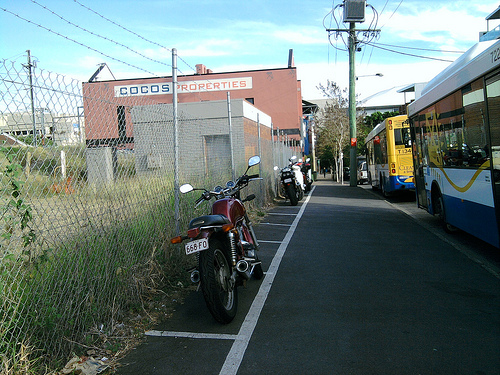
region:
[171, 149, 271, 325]
Motorcycle leaning against fence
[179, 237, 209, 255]
License on motorcycle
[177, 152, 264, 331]
Motorcycle next to bus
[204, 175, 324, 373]
White line next to motorcycles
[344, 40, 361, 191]
Wooden post is green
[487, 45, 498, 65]
722 on top of bus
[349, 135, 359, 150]
Red sign on wooden post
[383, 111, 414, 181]
Back of bus is yellow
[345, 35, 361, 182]
Wooden post next to bus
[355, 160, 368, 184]
White car in front of bus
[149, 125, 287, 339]
red motorcycle is parked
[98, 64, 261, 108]
white sign on building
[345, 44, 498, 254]
the buses are parked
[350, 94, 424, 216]
bus is yellow and blue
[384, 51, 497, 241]
bus is white and blue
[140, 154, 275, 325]
the motorcycle is red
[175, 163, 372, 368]
road lines are white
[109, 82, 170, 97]
the letters are blue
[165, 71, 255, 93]
the letters are orange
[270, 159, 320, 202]
the motorcycle is white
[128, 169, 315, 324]
The bike is parked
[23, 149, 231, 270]
The grass is tall and green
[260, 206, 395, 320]
The pavement has lines on it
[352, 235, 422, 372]
The pavement is dark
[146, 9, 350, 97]
The sky is blue and cloudy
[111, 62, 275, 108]
The building says Cocos properties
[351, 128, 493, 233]
The buses are parked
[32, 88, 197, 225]
The fence is metal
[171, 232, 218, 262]
The licence plate is white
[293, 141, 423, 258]
The ground has shadows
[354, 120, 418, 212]
A parked yellow bus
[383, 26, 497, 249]
A parked white and blue bus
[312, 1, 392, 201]
A power pole next to the road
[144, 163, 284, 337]
A red motorcycle parked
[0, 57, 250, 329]
Chain link fence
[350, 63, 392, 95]
A streetlight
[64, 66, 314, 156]
2 story building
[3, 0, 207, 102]
Barbed wire over chainlink fence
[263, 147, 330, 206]
Motorcycles parked by the fence in the center of the photo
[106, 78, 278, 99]
Name of the 2 story building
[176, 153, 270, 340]
the red colored bullet parked on the road side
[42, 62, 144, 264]
the iron mesh on the road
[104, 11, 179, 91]
the iron fencing of the factory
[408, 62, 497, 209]
the white colored bus on the road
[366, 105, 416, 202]
the yellow colored bus on the road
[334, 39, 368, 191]
the green color pole on the road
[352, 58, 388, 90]
the street light on the road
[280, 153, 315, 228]
the black colored bike parked on the road side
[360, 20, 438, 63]
the electrical wiring on the poles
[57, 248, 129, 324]
the green colored grass